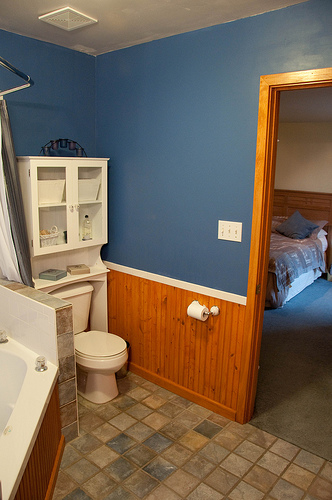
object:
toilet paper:
[185, 298, 209, 321]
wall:
[96, 6, 330, 427]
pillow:
[273, 211, 319, 240]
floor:
[49, 276, 331, 500]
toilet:
[48, 280, 130, 402]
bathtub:
[1, 331, 58, 498]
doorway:
[236, 65, 331, 463]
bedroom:
[247, 83, 330, 463]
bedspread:
[266, 215, 328, 307]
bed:
[264, 214, 329, 311]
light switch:
[216, 218, 243, 243]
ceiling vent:
[38, 4, 99, 33]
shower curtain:
[0, 95, 35, 292]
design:
[39, 138, 87, 161]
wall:
[1, 30, 98, 288]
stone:
[140, 410, 172, 433]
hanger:
[0, 55, 36, 100]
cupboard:
[15, 155, 111, 334]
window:
[76, 165, 102, 203]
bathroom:
[0, 1, 331, 498]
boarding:
[105, 260, 246, 422]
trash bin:
[115, 343, 130, 381]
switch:
[233, 229, 239, 241]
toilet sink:
[50, 280, 93, 337]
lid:
[74, 328, 128, 358]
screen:
[0, 159, 23, 283]